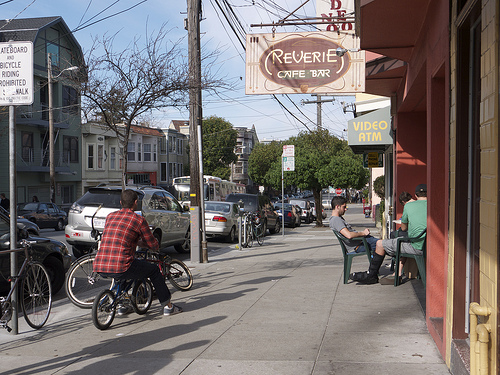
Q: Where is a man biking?
A: On the sidewalk.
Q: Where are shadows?
A: On the ground.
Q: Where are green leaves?
A: On trees.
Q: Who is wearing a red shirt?
A: Man riding bike.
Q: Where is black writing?
A: On white sign.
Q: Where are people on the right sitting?
A: On chairs.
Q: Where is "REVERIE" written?
A: On a sign.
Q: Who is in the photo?
A: Some people.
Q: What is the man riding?
A: Bike.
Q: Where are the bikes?
A: On the sidewalk.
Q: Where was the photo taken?
A: Outside somewhere.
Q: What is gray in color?
A: The sidewalk.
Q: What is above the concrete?
A: A sign.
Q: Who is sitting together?
A: Three men.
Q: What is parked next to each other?
A: Bikes.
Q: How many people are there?
A: Four.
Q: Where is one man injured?
A: Left leg.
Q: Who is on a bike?
A: Boy in plaid shirt.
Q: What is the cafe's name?
A: Reverie.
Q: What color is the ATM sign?
A: Blue and yellow.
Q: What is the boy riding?
A: A small bike.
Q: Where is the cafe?
A: To the right.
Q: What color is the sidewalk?
A: Grey.